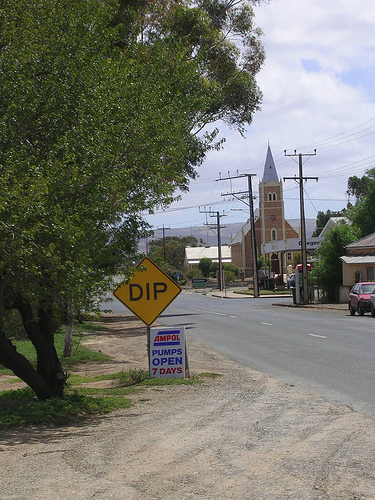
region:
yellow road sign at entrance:
[57, 249, 190, 350]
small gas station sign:
[124, 315, 219, 393]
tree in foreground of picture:
[0, 25, 226, 393]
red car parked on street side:
[321, 270, 364, 317]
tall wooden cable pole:
[249, 131, 335, 324]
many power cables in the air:
[189, 126, 342, 210]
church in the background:
[181, 152, 297, 294]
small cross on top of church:
[255, 132, 271, 156]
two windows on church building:
[263, 188, 281, 207]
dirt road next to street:
[64, 350, 347, 493]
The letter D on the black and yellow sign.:
[125, 276, 144, 303]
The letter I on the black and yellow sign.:
[140, 280, 154, 301]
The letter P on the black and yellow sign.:
[153, 278, 169, 301]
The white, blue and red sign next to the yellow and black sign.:
[143, 321, 192, 381]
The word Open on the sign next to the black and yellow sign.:
[151, 356, 183, 365]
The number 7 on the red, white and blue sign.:
[149, 365, 159, 376]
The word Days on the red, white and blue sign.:
[160, 365, 181, 376]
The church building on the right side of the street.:
[231, 135, 302, 277]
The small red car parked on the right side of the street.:
[343, 281, 372, 310]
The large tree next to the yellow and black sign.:
[0, 1, 212, 406]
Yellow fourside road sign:
[99, 225, 192, 333]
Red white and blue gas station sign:
[138, 313, 201, 391]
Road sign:
[109, 247, 208, 395]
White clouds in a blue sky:
[284, 7, 367, 128]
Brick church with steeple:
[217, 140, 319, 307]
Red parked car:
[335, 265, 370, 323]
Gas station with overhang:
[256, 228, 347, 303]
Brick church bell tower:
[244, 134, 308, 220]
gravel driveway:
[211, 357, 371, 490]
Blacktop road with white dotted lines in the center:
[204, 297, 370, 389]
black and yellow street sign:
[108, 252, 184, 333]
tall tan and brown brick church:
[232, 140, 305, 280]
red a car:
[345, 274, 374, 319]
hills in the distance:
[132, 214, 326, 250]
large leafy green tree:
[4, 1, 276, 401]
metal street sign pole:
[140, 323, 160, 379]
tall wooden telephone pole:
[275, 144, 320, 303]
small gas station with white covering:
[253, 230, 324, 306]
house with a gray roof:
[175, 239, 238, 286]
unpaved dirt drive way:
[0, 381, 374, 498]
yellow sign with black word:
[109, 250, 189, 340]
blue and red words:
[153, 325, 183, 378]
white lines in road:
[221, 310, 332, 358]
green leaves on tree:
[31, 125, 115, 258]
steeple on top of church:
[255, 139, 289, 195]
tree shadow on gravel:
[26, 407, 104, 460]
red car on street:
[342, 279, 368, 321]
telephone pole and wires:
[287, 134, 338, 221]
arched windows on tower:
[264, 190, 278, 209]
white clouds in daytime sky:
[283, 32, 348, 110]